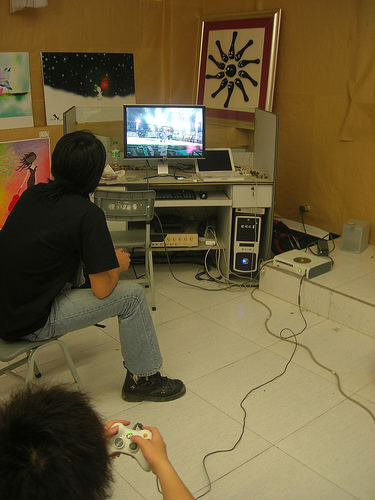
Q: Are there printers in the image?
A: No, there are no printers.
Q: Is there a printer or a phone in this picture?
A: No, there are no printers or phones.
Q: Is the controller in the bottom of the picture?
A: Yes, the controller is in the bottom of the image.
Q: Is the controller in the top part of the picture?
A: No, the controller is in the bottom of the image.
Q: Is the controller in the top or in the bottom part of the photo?
A: The controller is in the bottom of the image.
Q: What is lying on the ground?
A: The controller is lying on the ground.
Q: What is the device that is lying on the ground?
A: The device is a controller.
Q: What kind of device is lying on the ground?
A: The device is a controller.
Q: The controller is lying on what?
A: The controller is lying on the ground.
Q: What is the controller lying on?
A: The controller is lying on the ground.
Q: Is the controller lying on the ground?
A: Yes, the controller is lying on the ground.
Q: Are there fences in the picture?
A: No, there are no fences.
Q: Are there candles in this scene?
A: No, there are no candles.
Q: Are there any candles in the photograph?
A: No, there are no candles.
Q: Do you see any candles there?
A: No, there are no candles.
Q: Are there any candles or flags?
A: No, there are no candles or flags.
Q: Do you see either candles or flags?
A: No, there are no candles or flags.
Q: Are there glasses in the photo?
A: No, there are no glasses.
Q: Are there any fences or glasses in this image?
A: No, there are no glasses or fences.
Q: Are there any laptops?
A: Yes, there is a laptop.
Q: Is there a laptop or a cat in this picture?
A: Yes, there is a laptop.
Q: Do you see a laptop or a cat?
A: Yes, there is a laptop.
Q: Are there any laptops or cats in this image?
A: Yes, there is a laptop.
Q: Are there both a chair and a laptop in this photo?
A: Yes, there are both a laptop and a chair.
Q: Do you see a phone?
A: No, there are no phones.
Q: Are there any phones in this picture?
A: No, there are no phones.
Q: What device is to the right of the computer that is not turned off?
A: The device is a laptop.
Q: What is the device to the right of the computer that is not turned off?
A: The device is a laptop.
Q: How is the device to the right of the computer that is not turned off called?
A: The device is a laptop.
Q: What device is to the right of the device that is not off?
A: The device is a laptop.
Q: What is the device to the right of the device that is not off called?
A: The device is a laptop.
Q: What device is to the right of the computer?
A: The device is a laptop.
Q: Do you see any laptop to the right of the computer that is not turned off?
A: Yes, there is a laptop to the right of the computer.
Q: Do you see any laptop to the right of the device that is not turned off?
A: Yes, there is a laptop to the right of the computer.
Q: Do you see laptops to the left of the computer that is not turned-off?
A: No, the laptop is to the right of the computer.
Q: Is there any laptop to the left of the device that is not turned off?
A: No, the laptop is to the right of the computer.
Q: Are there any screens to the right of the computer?
A: No, there is a laptop to the right of the computer.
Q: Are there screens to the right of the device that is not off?
A: No, there is a laptop to the right of the computer.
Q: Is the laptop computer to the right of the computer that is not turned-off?
A: Yes, the laptop computer is to the right of the computer.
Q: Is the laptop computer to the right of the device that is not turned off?
A: Yes, the laptop computer is to the right of the computer.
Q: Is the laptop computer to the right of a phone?
A: No, the laptop computer is to the right of the computer.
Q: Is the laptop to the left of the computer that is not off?
A: No, the laptop is to the right of the computer.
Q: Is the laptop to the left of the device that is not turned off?
A: No, the laptop is to the right of the computer.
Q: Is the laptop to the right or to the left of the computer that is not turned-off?
A: The laptop is to the right of the computer.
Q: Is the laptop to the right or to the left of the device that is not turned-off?
A: The laptop is to the right of the computer.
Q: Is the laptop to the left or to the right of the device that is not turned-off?
A: The laptop is to the right of the computer.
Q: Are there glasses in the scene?
A: No, there are no glasses.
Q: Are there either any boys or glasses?
A: No, there are no glasses or boys.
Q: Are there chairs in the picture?
A: Yes, there is a chair.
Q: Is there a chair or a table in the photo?
A: Yes, there is a chair.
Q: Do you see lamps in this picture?
A: No, there are no lamps.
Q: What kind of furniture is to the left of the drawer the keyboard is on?
A: The piece of furniture is a chair.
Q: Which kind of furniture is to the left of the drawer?
A: The piece of furniture is a chair.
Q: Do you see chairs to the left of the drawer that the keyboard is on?
A: Yes, there is a chair to the left of the drawer.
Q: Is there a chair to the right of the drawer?
A: No, the chair is to the left of the drawer.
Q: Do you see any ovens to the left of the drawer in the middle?
A: No, there is a chair to the left of the drawer.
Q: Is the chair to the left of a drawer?
A: Yes, the chair is to the left of a drawer.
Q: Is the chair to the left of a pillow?
A: No, the chair is to the left of a drawer.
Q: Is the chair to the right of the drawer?
A: No, the chair is to the left of the drawer.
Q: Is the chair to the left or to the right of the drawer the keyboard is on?
A: The chair is to the left of the drawer.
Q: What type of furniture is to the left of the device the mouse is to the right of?
A: The piece of furniture is a chair.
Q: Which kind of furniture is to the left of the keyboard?
A: The piece of furniture is a chair.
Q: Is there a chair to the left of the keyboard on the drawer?
A: Yes, there is a chair to the left of the keyboard.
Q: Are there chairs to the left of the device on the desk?
A: Yes, there is a chair to the left of the keyboard.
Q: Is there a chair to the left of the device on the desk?
A: Yes, there is a chair to the left of the keyboard.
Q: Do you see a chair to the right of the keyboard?
A: No, the chair is to the left of the keyboard.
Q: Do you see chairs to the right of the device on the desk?
A: No, the chair is to the left of the keyboard.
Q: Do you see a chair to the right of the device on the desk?
A: No, the chair is to the left of the keyboard.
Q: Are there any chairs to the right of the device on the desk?
A: No, the chair is to the left of the keyboard.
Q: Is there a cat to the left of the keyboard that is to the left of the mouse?
A: No, there is a chair to the left of the keyboard.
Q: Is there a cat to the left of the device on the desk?
A: No, there is a chair to the left of the keyboard.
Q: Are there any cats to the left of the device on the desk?
A: No, there is a chair to the left of the keyboard.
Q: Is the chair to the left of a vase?
A: No, the chair is to the left of a keyboard.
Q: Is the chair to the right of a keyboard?
A: No, the chair is to the left of a keyboard.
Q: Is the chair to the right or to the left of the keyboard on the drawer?
A: The chair is to the left of the keyboard.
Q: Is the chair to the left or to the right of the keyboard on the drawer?
A: The chair is to the left of the keyboard.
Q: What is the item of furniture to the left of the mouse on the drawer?
A: The piece of furniture is a chair.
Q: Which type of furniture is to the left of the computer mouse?
A: The piece of furniture is a chair.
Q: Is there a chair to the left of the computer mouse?
A: Yes, there is a chair to the left of the computer mouse.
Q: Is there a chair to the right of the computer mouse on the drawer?
A: No, the chair is to the left of the mouse.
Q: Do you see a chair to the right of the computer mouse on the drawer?
A: No, the chair is to the left of the mouse.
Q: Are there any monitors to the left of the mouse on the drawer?
A: No, there is a chair to the left of the computer mouse.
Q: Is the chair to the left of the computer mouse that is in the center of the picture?
A: Yes, the chair is to the left of the mouse.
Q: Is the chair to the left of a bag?
A: No, the chair is to the left of the mouse.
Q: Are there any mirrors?
A: No, there are no mirrors.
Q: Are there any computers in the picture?
A: Yes, there is a computer.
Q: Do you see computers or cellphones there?
A: Yes, there is a computer.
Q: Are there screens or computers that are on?
A: Yes, the computer is on.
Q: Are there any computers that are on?
A: Yes, there is a computer that is on.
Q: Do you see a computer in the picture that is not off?
A: Yes, there is a computer that is on .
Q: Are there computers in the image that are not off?
A: Yes, there is a computer that is on.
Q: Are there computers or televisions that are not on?
A: No, there is a computer but it is on.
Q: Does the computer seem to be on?
A: Yes, the computer is on.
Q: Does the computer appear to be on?
A: Yes, the computer is on.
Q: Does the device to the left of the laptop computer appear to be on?
A: Yes, the computer is on.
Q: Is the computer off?
A: No, the computer is on.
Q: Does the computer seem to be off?
A: No, the computer is on.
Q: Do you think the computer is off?
A: No, the computer is on.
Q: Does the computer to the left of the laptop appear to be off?
A: No, the computer is on.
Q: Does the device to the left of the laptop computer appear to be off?
A: No, the computer is on.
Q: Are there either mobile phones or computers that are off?
A: No, there is a computer but it is on.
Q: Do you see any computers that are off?
A: No, there is a computer but it is on.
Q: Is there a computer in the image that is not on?
A: No, there is a computer but it is on.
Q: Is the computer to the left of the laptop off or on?
A: The computer is on.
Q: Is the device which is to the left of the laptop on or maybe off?
A: The computer is on.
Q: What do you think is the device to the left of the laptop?
A: The device is a computer.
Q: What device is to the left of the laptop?
A: The device is a computer.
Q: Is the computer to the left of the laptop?
A: Yes, the computer is to the left of the laptop.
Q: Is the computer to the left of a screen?
A: No, the computer is to the left of the laptop.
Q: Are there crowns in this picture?
A: No, there are no crowns.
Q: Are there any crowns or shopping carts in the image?
A: No, there are no crowns or shopping carts.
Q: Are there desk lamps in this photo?
A: No, there are no desk lamps.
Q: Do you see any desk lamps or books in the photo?
A: No, there are no desk lamps or books.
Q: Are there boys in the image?
A: No, there are no boys.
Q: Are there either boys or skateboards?
A: No, there are no boys or skateboards.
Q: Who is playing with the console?
A: The guy is playing with the console.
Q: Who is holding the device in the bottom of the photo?
A: The guy is holding the controller.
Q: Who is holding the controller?
A: The guy is holding the controller.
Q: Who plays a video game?
A: The guy plays a video game.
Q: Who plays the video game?
A: The guy plays a video game.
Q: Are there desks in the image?
A: Yes, there is a desk.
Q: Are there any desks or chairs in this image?
A: Yes, there is a desk.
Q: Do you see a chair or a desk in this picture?
A: Yes, there is a desk.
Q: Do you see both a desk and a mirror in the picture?
A: No, there is a desk but no mirrors.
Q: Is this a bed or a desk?
A: This is a desk.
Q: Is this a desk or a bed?
A: This is a desk.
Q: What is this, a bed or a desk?
A: This is a desk.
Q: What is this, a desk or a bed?
A: This is a desk.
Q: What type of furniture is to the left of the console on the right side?
A: The piece of furniture is a desk.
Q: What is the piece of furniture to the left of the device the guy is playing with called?
A: The piece of furniture is a desk.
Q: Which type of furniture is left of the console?
A: The piece of furniture is a desk.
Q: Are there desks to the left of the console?
A: Yes, there is a desk to the left of the console.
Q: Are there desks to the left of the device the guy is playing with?
A: Yes, there is a desk to the left of the console.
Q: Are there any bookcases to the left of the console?
A: No, there is a desk to the left of the console.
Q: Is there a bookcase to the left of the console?
A: No, there is a desk to the left of the console.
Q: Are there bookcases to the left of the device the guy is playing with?
A: No, there is a desk to the left of the console.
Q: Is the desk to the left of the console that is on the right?
A: Yes, the desk is to the left of the console.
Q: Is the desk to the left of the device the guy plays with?
A: Yes, the desk is to the left of the console.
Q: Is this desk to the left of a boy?
A: No, the desk is to the left of the console.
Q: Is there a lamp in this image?
A: No, there are no lamps.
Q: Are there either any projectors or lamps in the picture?
A: No, there are no lamps or projectors.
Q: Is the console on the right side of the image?
A: Yes, the console is on the right of the image.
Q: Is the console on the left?
A: No, the console is on the right of the image.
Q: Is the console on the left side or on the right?
A: The console is on the right of the image.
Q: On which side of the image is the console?
A: The console is on the right of the image.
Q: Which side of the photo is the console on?
A: The console is on the right of the image.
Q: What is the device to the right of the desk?
A: The device is a console.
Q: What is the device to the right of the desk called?
A: The device is a console.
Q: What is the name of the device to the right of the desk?
A: The device is a console.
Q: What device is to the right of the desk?
A: The device is a console.